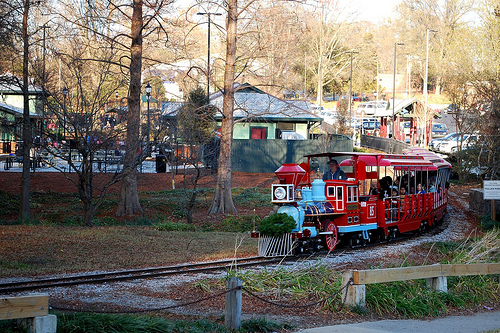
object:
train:
[250, 146, 454, 257]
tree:
[0, 0, 71, 218]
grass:
[151, 218, 201, 233]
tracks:
[0, 253, 295, 292]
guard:
[322, 161, 347, 182]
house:
[160, 82, 320, 141]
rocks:
[0, 188, 500, 332]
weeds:
[451, 225, 500, 265]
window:
[275, 123, 295, 132]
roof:
[373, 99, 442, 118]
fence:
[339, 263, 500, 305]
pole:
[392, 41, 402, 142]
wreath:
[259, 212, 295, 238]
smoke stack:
[273, 162, 306, 190]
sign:
[482, 180, 500, 199]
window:
[346, 185, 350, 203]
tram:
[359, 135, 412, 153]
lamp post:
[207, 11, 215, 107]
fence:
[202, 140, 355, 172]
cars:
[432, 135, 479, 154]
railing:
[351, 263, 500, 284]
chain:
[48, 280, 354, 312]